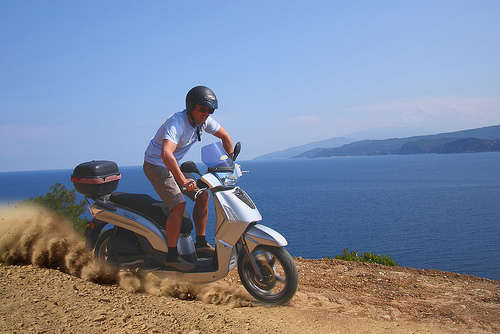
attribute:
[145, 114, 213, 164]
shirt — blue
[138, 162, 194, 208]
shorts — tan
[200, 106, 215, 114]
sunglasses — black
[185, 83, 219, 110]
helmet — black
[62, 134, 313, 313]
scooter — silver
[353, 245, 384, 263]
patch — green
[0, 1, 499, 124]
sky — blue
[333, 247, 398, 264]
grass — green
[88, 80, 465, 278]
water — calm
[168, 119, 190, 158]
shirt — blue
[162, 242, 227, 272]
shoes — brown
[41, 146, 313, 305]
scooter — silver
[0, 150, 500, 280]
water — blue, calm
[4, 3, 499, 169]
sky — blue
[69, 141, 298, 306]
moped — Silver 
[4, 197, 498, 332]
road — dirt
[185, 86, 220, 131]
helmet — black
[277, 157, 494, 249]
water — calm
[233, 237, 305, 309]
wheel — black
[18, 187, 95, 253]
tree — green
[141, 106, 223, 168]
shirt — blue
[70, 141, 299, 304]
scooter — silver